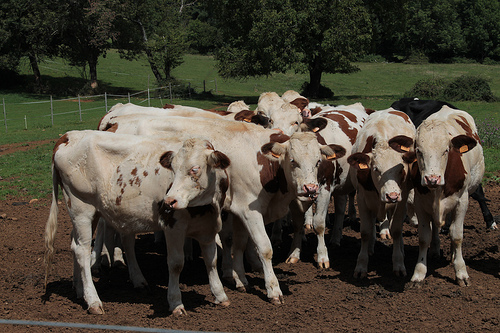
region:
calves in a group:
[23, 72, 489, 317]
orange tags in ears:
[270, 135, 337, 210]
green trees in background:
[224, 3, 376, 92]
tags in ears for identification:
[397, 110, 479, 193]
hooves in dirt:
[209, 283, 300, 317]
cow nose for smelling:
[285, 177, 323, 202]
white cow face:
[155, 127, 221, 221]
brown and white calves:
[355, 97, 476, 294]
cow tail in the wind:
[25, 162, 72, 299]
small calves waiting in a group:
[1, 109, 462, 311]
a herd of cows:
[24, 51, 499, 326]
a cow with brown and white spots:
[37, 110, 238, 321]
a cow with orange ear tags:
[385, 95, 491, 302]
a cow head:
[150, 133, 231, 221]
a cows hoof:
[244, 249, 300, 319]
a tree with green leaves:
[210, 16, 383, 86]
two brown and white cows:
[357, 87, 498, 301]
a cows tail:
[14, 114, 71, 294]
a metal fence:
[2, 67, 97, 124]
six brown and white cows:
[19, 50, 496, 332]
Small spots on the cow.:
[107, 169, 169, 198]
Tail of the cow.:
[36, 239, 57, 271]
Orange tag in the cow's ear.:
[455, 138, 475, 169]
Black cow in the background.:
[369, 99, 435, 125]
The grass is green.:
[347, 86, 386, 96]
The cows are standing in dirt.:
[357, 300, 444, 318]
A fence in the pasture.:
[43, 89, 111, 123]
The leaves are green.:
[258, 36, 315, 46]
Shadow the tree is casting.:
[48, 74, 117, 94]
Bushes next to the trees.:
[429, 75, 475, 96]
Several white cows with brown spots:
[43, 57, 484, 329]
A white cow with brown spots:
[41, 125, 233, 323]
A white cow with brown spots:
[242, 122, 314, 297]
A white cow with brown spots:
[421, 104, 478, 305]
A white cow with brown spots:
[361, 100, 400, 272]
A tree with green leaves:
[256, 0, 373, 87]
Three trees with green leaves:
[8, 0, 206, 84]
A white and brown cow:
[48, 119, 241, 316]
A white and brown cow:
[407, 97, 486, 290]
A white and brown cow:
[233, 118, 325, 302]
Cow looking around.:
[139, 126, 249, 266]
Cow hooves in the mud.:
[249, 287, 301, 309]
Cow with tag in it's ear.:
[352, 127, 374, 172]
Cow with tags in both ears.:
[393, 124, 480, 174]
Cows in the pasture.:
[101, 73, 478, 275]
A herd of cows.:
[37, 79, 450, 269]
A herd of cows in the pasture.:
[64, 72, 499, 269]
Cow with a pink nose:
[186, 91, 395, 214]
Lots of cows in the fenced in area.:
[34, 76, 475, 262]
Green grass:
[26, 65, 153, 160]